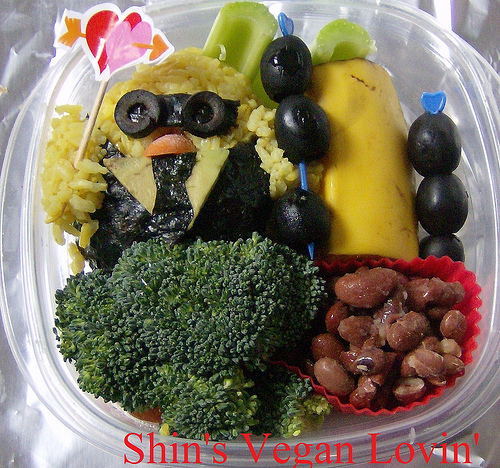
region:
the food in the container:
[42, 0, 483, 440]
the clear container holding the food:
[0, 2, 498, 467]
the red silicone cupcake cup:
[270, 255, 482, 415]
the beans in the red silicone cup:
[298, 265, 468, 407]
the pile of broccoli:
[49, 235, 327, 440]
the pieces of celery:
[202, 0, 374, 107]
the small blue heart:
[420, 90, 446, 114]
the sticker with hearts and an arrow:
[50, 2, 174, 82]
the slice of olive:
[182, 90, 224, 135]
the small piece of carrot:
[143, 133, 195, 155]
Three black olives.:
[405, 110, 472, 269]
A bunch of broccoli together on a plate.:
[54, 237, 336, 439]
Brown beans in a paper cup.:
[307, 261, 479, 416]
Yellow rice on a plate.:
[34, 47, 322, 273]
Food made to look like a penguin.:
[40, 44, 330, 282]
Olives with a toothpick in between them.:
[255, 8, 333, 264]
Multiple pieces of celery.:
[197, 0, 379, 115]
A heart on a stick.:
[49, 4, 176, 169]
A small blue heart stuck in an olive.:
[414, 86, 451, 122]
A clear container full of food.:
[0, 0, 498, 465]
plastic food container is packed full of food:
[0, 1, 497, 465]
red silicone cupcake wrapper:
[264, 256, 483, 416]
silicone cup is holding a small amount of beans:
[268, 249, 480, 413]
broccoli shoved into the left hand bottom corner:
[51, 235, 321, 437]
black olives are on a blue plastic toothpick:
[403, 88, 470, 259]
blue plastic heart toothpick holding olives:
[258, 12, 333, 260]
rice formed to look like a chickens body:
[39, 48, 319, 263]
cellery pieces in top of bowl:
[210, 3, 373, 105]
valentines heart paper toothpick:
[56, 5, 170, 174]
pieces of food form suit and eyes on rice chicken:
[91, 85, 308, 272]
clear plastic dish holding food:
[2, 8, 499, 457]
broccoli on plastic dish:
[56, 250, 317, 448]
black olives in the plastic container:
[265, 34, 467, 251]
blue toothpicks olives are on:
[271, 12, 468, 258]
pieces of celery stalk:
[204, 5, 373, 103]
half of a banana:
[311, 57, 422, 258]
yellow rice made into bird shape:
[32, 44, 319, 244]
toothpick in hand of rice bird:
[71, 74, 111, 152]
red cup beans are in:
[303, 246, 484, 423]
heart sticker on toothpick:
[56, 2, 169, 76]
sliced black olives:
[113, 91, 225, 136]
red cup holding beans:
[290, 254, 481, 414]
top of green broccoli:
[49, 240, 324, 425]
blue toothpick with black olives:
[260, 14, 331, 254]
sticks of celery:
[202, 1, 374, 66]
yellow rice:
[47, 103, 102, 248]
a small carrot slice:
[141, 134, 201, 157]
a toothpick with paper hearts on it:
[62, 8, 171, 166]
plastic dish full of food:
[2, 0, 499, 464]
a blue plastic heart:
[419, 91, 445, 111]